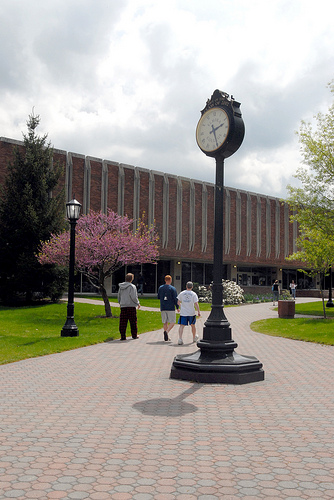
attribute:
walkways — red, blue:
[225, 287, 289, 346]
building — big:
[74, 172, 328, 264]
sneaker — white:
[177, 337, 183, 345]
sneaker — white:
[191, 335, 198, 342]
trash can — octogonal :
[277, 296, 296, 317]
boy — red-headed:
[156, 272, 179, 342]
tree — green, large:
[9, 133, 63, 313]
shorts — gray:
[138, 302, 233, 335]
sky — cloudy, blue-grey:
[1, 2, 325, 207]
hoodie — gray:
[115, 277, 141, 308]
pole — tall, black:
[59, 198, 90, 336]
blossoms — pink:
[32, 207, 158, 264]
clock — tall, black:
[195, 96, 277, 182]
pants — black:
[116, 303, 145, 342]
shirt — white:
[176, 289, 199, 316]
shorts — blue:
[175, 314, 200, 326]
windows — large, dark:
[180, 262, 221, 290]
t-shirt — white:
[175, 290, 199, 318]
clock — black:
[193, 88, 245, 161]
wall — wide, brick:
[10, 137, 332, 261]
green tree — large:
[295, 101, 331, 320]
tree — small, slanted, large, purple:
[34, 207, 159, 315]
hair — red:
[164, 276, 171, 281]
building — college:
[1, 136, 333, 293]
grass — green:
[250, 297, 333, 346]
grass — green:
[82, 295, 236, 311]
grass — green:
[0, 299, 201, 365]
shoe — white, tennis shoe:
[189, 334, 203, 341]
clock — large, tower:
[192, 91, 242, 160]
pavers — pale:
[4, 292, 332, 498]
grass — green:
[2, 296, 178, 358]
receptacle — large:
[274, 294, 298, 319]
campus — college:
[1, 295, 333, 499]